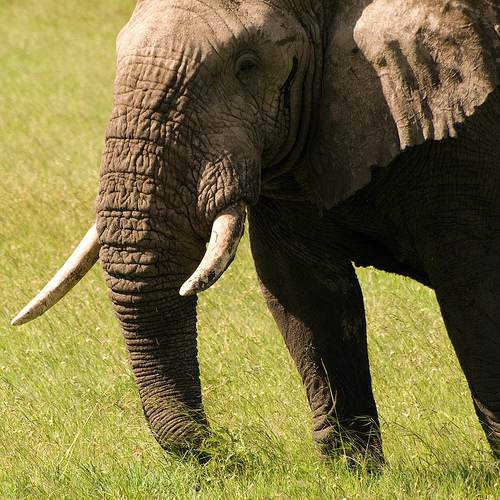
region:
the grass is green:
[27, 385, 110, 457]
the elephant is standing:
[105, 7, 498, 493]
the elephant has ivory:
[182, 182, 251, 322]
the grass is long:
[39, 377, 124, 490]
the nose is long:
[92, 30, 237, 495]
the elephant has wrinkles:
[94, 6, 406, 497]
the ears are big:
[291, 5, 488, 231]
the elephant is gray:
[78, 1, 487, 486]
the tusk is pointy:
[10, 198, 133, 373]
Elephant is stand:
[86, 3, 497, 498]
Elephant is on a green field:
[13, 2, 495, 492]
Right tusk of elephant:
[166, 197, 251, 297]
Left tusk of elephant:
[7, 214, 102, 351]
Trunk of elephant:
[81, 123, 219, 474]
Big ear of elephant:
[292, 6, 492, 213]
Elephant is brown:
[16, 1, 498, 484]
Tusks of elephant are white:
[1, 204, 247, 339]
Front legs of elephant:
[247, 254, 494, 491]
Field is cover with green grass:
[6, 4, 110, 498]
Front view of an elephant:
[8, 1, 498, 475]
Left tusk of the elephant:
[175, 208, 249, 300]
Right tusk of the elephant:
[8, 214, 108, 328]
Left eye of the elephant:
[230, 52, 260, 72]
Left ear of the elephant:
[292, 2, 496, 209]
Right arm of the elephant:
[243, 213, 393, 458]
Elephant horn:
[100, 65, 211, 470]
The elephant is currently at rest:
[10, 1, 497, 471]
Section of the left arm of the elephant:
[400, 185, 496, 450]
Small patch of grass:
[170, 407, 285, 474]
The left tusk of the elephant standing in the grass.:
[2, 245, 104, 327]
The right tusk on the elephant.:
[182, 202, 244, 297]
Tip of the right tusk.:
[170, 282, 198, 301]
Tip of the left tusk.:
[9, 315, 24, 327]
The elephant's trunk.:
[98, 222, 229, 498]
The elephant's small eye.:
[222, 48, 262, 80]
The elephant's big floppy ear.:
[317, 0, 493, 203]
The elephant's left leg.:
[255, 229, 409, 481]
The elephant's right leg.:
[417, 168, 499, 488]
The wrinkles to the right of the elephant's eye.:
[279, 26, 315, 188]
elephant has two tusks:
[7, 134, 286, 336]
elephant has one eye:
[217, 26, 283, 96]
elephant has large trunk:
[82, 16, 252, 486]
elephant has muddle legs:
[252, 191, 498, 478]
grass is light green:
[2, 8, 498, 498]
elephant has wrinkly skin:
[80, 31, 252, 446]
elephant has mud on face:
[261, 8, 307, 204]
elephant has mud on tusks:
[167, 191, 256, 298]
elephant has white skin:
[111, 4, 304, 65]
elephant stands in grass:
[218, 338, 488, 499]